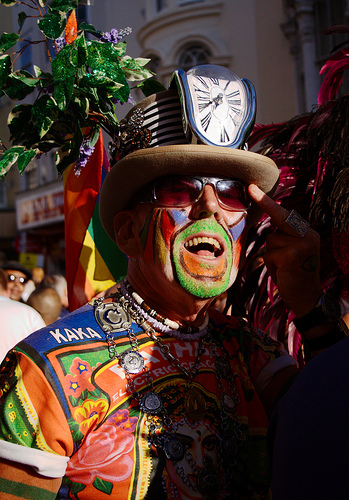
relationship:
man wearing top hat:
[0, 68, 273, 497] [24, 36, 287, 190]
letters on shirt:
[51, 324, 101, 342] [10, 282, 294, 496]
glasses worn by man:
[131, 164, 254, 217] [107, 103, 251, 347]